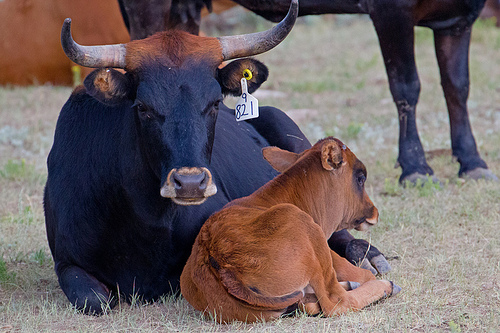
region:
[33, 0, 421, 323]
two cows laying on the ground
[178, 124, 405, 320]
brown baby cow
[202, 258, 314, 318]
tail curled under the body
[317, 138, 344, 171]
ear on the side of the head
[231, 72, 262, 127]
tag in the ear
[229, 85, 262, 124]
numbers on the tag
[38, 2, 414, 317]
baby cow laying next to an adult cow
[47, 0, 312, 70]
horns coming out of the head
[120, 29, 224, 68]
brown fur on the top of the head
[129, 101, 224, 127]
small eyes on either side of the head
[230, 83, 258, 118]
white tag in the bulls ear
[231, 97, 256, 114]
numbers on the white tag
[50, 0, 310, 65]
horns on the bull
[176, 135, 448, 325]
small calf laying on the ground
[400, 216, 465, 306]
grass on the ground is light green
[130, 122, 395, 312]
calf is laying next to the bull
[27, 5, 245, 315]
bull is laying down on the ground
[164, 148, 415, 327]
the calf is brown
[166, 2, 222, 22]
utters on a cow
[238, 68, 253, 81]
yellow part of the tag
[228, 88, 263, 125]
numbers written on the tag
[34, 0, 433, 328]
two cows laying on the grass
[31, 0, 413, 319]
baby cow laying by an adult cow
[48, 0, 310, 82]
two horns sticking out of the head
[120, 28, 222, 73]
top of the head is brown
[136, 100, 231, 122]
two eyes on either side of the head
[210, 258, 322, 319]
tail is curled under body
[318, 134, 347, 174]
brown ear on the side of the head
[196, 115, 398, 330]
the baby cow is resting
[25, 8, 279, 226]
the cow has horns